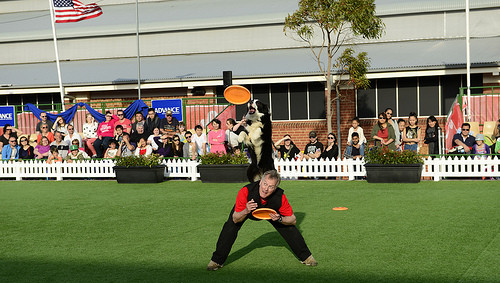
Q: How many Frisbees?
A: 3.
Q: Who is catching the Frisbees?
A: Dog.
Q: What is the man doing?
A: Letting dog jump on his back.